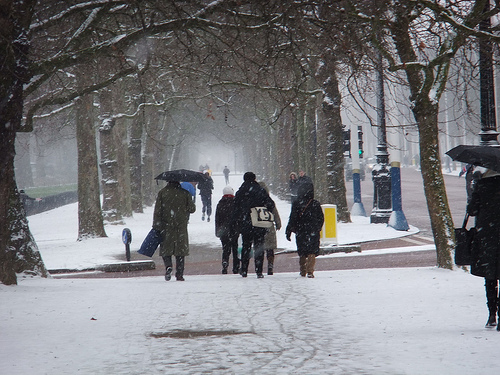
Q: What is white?
A: Snow.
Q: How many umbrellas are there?
A: Two.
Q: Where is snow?
A: On the ground.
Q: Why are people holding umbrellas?
A: To block snow.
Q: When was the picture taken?
A: Daytime.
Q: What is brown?
A: Trees.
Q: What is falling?
A: Snow.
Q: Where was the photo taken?
A: On a snowy street.